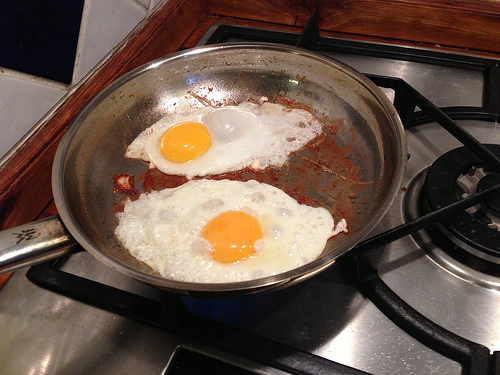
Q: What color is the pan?
A: Silver.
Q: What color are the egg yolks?
A: Yellow.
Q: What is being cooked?
A: Eggs.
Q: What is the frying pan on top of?
A: A stove.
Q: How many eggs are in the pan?
A: Two.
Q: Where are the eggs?
A: In the frying pan.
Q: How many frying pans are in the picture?
A: One.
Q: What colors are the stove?
A: Silver and black.